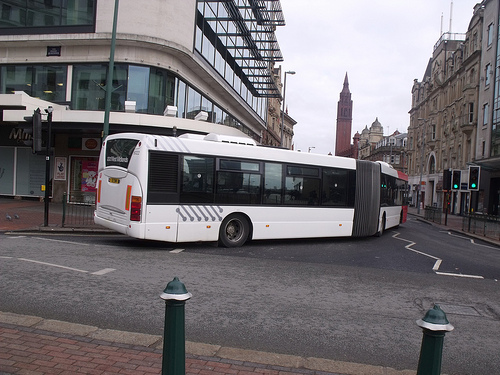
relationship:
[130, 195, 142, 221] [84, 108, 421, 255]
back light on bus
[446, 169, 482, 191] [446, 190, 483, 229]
signal on pole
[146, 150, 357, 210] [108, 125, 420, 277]
windows on bus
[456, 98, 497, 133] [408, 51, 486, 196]
window on building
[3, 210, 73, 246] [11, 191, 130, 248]
birds on sidewalk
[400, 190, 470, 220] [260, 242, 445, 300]
fence by ground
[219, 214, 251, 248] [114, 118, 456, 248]
bus tire on bus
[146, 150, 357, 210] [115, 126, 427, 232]
windows on bus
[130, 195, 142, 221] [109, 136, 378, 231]
back light on bus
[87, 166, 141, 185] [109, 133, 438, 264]
plate on bus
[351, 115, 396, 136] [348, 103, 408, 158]
roof on building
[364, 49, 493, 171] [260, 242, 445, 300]
building by ground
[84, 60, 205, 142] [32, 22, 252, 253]
window on building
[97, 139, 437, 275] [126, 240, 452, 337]
bus on street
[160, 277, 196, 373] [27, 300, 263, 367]
pole on sidewalk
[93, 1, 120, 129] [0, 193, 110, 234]
pole on sidewalk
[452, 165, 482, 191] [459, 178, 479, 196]
signal with light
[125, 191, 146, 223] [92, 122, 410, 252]
back light of bus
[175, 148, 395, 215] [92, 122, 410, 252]
windows on side of bus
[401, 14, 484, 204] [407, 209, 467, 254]
building on right side of street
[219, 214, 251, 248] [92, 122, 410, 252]
bus tire of bus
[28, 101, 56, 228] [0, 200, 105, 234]
traffic light on sidewalk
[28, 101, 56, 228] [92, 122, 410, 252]
traffic light behind bus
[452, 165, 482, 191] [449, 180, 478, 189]
signal displaying lights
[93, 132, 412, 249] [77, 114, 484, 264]
bus going around a corner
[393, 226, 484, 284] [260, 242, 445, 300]
line on ground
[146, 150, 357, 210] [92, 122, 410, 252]
windows of a bus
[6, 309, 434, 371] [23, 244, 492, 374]
bricks on ground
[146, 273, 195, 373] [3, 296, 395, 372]
pole embedded in sidewalk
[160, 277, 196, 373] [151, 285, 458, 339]
pole with reflective strips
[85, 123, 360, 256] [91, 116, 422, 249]
second segment of bus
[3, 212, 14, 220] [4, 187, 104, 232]
birds on city sidewalk